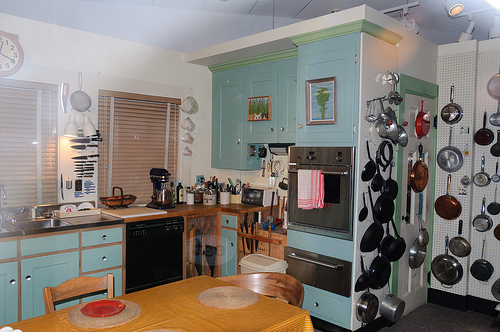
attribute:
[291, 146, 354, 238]
stove. — gray.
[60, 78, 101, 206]
wall — Shiny 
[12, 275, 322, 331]
table — kitchen , yellow table , brown.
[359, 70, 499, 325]
pots and pans — kitchen , assorted 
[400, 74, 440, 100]
wooden trim — mint green.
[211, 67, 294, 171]
cabinets — blue.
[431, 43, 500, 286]
pans — Shiny 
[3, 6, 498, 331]
photo — small.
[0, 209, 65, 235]
sink — silver.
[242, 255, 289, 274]
trash can — off-white.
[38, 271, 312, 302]
two chairs — brown.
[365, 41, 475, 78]
wall — white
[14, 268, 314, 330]
cloth — Gold table